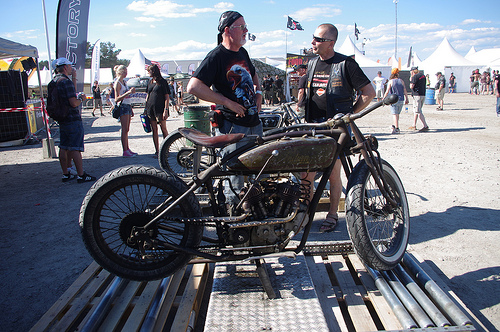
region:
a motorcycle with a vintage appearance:
[76, 94, 411, 279]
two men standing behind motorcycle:
[76, 9, 411, 279]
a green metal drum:
[182, 104, 212, 150]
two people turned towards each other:
[111, 61, 171, 157]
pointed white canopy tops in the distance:
[336, 35, 498, 95]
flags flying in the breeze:
[283, 14, 368, 65]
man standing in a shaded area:
[24, 55, 95, 193]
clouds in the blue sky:
[1, 1, 498, 66]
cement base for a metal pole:
[33, 58, 55, 156]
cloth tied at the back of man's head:
[215, 9, 247, 48]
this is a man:
[198, 11, 270, 151]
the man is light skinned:
[227, 29, 244, 50]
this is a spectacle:
[233, 24, 254, 28]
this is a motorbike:
[106, 140, 378, 251]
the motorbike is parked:
[92, 153, 338, 259]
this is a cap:
[52, 57, 77, 66]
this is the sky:
[400, 12, 474, 39]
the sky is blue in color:
[418, 0, 455, 17]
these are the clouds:
[411, 22, 445, 39]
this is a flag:
[279, 10, 300, 35]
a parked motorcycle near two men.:
[74, 68, 440, 287]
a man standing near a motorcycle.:
[263, 16, 394, 236]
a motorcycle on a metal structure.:
[73, 100, 452, 293]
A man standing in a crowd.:
[36, 37, 106, 182]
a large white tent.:
[420, 26, 498, 100]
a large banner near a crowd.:
[46, 0, 106, 81]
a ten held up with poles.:
[0, 25, 61, 161]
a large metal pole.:
[143, 233, 197, 328]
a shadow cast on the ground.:
[351, 194, 498, 234]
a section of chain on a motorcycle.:
[152, 203, 300, 244]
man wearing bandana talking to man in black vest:
[185, 7, 260, 203]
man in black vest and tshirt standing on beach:
[295, 21, 375, 231]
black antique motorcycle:
[75, 91, 410, 293]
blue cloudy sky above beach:
[0, 0, 495, 60]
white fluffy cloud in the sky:
[125, 0, 230, 15]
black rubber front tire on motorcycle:
[345, 155, 410, 267]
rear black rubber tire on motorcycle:
[76, 162, 202, 277]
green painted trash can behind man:
[180, 100, 210, 145]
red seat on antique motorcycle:
[175, 125, 241, 145]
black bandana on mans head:
[213, 6, 240, 44]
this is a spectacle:
[318, 35, 333, 42]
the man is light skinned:
[207, 87, 234, 110]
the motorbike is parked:
[210, 141, 347, 293]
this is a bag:
[40, 81, 64, 112]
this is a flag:
[284, 12, 309, 36]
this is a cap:
[48, 45, 75, 71]